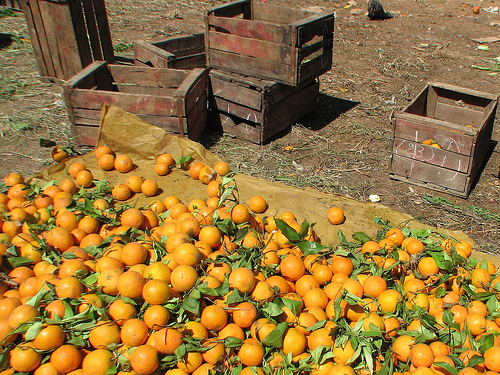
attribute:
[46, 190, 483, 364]
oranges — batch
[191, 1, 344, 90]
wooden crate — brown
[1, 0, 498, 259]
dirt — brown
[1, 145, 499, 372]
leaves — green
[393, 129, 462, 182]
writing — white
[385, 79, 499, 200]
box — wooden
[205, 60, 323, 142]
crate — wood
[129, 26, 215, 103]
crate — wood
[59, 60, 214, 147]
crate — wooden, brown, wood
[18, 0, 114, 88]
crate — wooden, brown, wood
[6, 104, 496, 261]
bag — brown, paper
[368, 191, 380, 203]
debri — white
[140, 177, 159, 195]
orange fruit — ripe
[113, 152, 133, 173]
orange fruit — ripe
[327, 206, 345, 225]
orange fruit — ripe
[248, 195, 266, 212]
orange fruit — ripe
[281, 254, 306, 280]
orange fruit — ripe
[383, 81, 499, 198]
crate — brown, wooden, wood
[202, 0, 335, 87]
crate — wooden, brown, wood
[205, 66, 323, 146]
crate — wooden, brown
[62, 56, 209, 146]
crate — wooden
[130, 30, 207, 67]
crate — wooden, brown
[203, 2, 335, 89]
wooden crate — brown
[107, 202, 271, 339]
oranges — orange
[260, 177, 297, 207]
brown paper —  brown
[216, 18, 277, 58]
number sign — red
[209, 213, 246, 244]
leaf — green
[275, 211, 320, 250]
leaf — green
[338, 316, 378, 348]
leaf — green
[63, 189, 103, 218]
leaf — green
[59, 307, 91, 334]
leaf — green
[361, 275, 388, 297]
orange fruit — ripe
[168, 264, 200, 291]
orange fruit — ripe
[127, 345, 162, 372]
orange fruit — ripe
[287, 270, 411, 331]
fruit — orange, ripe